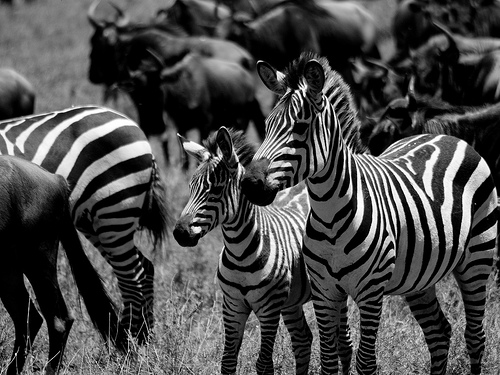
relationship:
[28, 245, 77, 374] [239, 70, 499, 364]
leg of zebra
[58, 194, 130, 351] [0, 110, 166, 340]
tail of zebra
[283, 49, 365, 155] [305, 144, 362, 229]
hair on neck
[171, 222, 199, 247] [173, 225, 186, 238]
snout has tip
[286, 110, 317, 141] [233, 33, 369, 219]
eye on head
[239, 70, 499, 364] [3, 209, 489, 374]
zebra on grass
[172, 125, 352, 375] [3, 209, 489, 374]
colt on grass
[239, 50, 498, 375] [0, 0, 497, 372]
zebra on grass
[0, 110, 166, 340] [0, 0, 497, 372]
zebra on grass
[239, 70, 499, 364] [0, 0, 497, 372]
zebra on grass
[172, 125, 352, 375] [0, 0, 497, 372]
colt on grass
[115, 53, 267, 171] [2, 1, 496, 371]
buffalo in field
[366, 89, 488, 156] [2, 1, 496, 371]
buffalo in field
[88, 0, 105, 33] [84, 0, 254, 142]
horns on wildebeest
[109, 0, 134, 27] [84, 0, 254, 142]
horns on wildebeest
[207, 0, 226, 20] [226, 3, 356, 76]
horns on wildebeest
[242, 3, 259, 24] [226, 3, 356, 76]
horns on wildebeest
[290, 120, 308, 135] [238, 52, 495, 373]
eye of zebra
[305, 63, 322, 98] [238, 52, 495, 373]
ear on zebra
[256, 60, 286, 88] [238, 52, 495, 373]
ear on zebra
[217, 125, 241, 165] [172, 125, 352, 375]
ear on colt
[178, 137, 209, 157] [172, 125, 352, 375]
ear on colt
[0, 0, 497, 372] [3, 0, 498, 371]
grass on plain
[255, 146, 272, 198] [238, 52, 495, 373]
black nose on zebra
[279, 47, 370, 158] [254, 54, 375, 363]
hair on zebra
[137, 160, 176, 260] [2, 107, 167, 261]
tail of zebra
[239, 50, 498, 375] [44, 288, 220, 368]
zebra on grass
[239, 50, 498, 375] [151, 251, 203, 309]
zebra in grass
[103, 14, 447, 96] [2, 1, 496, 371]
oxen in field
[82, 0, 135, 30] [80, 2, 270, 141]
horns on bull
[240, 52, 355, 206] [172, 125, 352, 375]
head of colt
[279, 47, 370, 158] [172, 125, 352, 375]
hair of colt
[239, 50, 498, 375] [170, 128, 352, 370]
zebra next to colt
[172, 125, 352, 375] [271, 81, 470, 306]
colt standing next to zebra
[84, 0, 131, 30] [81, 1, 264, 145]
horns of water buffalo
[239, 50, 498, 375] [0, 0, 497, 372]
zebra standing in grass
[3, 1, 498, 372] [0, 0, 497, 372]
animals in grass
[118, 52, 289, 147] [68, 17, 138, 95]
buffalo background ox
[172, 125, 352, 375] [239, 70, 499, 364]
colt standing next to zebra